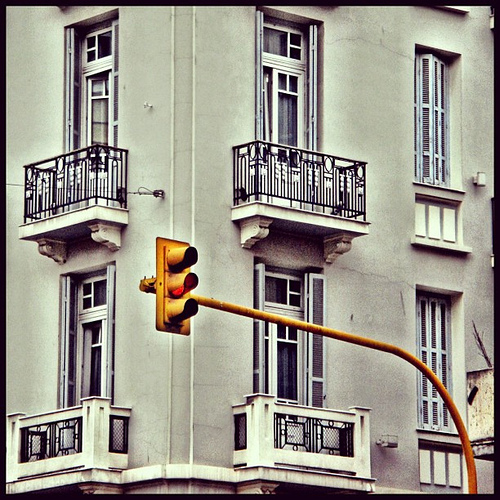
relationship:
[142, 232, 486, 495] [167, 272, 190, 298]
traffic light has light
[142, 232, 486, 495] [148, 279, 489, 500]
traffic light on pole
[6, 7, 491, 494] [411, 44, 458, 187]
building has window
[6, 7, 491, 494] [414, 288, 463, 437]
building has window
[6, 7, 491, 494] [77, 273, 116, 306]
building has window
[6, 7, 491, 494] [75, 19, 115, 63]
building has window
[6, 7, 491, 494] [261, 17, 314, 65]
building has window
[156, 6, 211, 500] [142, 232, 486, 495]
building corner near traffic light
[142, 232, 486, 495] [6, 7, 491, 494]
traffic light near building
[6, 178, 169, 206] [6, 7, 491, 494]
wire attached to building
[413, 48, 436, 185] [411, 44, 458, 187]
shutter on window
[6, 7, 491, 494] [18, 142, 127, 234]
building has balcony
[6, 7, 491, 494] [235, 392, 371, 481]
building has balcony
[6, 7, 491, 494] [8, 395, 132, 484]
building has balcony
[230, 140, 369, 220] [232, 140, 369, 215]
balcony has railing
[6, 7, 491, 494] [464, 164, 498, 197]
building has light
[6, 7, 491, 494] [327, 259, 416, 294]
building has crack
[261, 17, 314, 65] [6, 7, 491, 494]
window on building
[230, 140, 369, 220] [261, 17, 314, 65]
balcony in front of window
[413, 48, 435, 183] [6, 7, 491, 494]
shutter on building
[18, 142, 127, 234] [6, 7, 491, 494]
balcony protruding from building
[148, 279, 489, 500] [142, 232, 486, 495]
pole holding up traffic light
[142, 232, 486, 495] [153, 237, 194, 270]
traffic light has top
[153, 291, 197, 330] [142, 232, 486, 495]
bottom on traffic light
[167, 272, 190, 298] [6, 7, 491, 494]
light on building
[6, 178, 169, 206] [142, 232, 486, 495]
wire hanging over traffic light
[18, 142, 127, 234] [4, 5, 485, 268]
balcony on second floor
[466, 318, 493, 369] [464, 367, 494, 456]
tree branch on patio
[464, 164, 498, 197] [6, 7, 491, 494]
light on building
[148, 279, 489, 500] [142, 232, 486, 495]
pole holding traffic light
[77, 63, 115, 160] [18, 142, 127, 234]
patio door over balcony